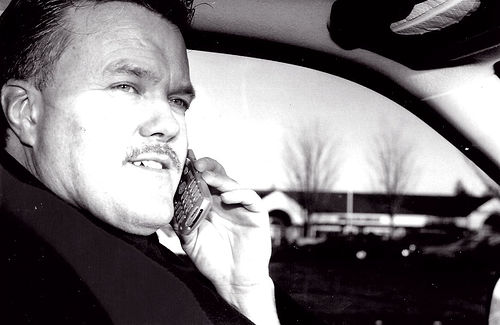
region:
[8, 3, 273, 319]
a man on a cell phone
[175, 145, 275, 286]
a cell phone in hand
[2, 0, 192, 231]
a head of a man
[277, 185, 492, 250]
a shopping mall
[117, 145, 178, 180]
a mans mouth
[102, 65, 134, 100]
a mans right eye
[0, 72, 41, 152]
a man right ear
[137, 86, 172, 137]
a mans nose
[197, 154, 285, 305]
a mans left hand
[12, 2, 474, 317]
a man on a cell phone in a car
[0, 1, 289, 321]
Man speaking on phone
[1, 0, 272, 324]
Man wearing black jacket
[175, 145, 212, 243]
Small grey button phone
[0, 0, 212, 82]
Man with short black hair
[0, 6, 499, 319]
Man sitting in a car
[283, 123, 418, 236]
Two trees in the background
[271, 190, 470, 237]
Wooded fence in the background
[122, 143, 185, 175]
Man with a short hair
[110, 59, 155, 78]
Thick black eye brows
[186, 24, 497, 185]
Frame of a car door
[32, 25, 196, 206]
This is a man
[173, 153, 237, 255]
This is a cell phone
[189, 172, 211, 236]
This is a flip phone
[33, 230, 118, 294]
This is a jacket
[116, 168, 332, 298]
The photo is black and white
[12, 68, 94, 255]
This is an ear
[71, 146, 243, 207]
This is a mouth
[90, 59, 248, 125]
These are eyes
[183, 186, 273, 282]
This is a hand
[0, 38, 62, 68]
The hair is short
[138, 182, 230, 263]
This is a cell phone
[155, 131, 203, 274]
This is a flip phone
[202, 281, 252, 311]
This is a wrist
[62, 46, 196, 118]
These are eyes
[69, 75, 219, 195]
This is a mouth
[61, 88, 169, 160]
This is a moustache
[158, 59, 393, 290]
This is a window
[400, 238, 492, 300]
This is a car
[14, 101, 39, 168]
This is an ear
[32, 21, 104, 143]
The hair is short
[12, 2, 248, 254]
man holding his phone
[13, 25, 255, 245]
man is talking on his phone